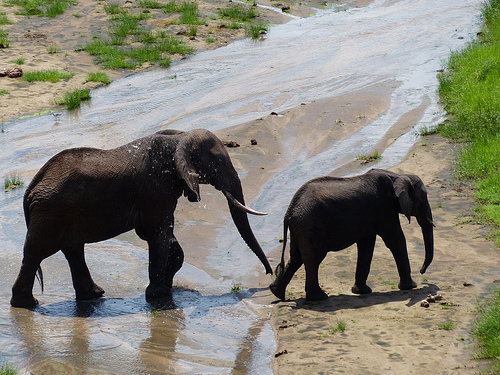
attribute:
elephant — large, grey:
[289, 100, 447, 346]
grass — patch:
[17, 67, 75, 82]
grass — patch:
[84, 69, 113, 86]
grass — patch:
[54, 87, 94, 109]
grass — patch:
[440, 3, 498, 235]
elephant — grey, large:
[256, 144, 446, 334]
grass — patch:
[113, 28, 194, 77]